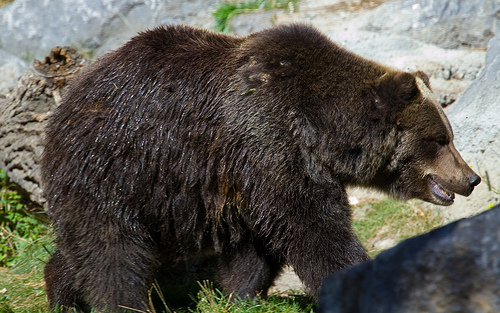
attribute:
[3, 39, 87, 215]
log — rough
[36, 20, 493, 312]
bear — furry, panting, grizzly, brown, walking, large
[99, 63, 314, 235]
fur — brown, shiny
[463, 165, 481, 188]
nose — black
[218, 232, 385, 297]
front legs — large